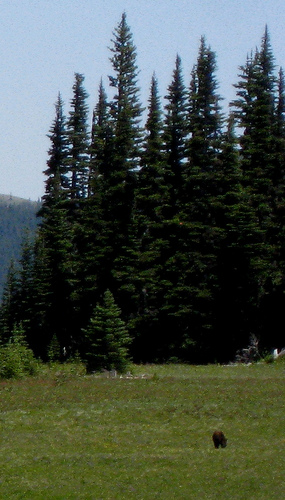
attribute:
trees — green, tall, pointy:
[19, 34, 285, 353]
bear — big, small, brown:
[205, 427, 243, 455]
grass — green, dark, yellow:
[72, 379, 270, 490]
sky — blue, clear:
[17, 5, 188, 114]